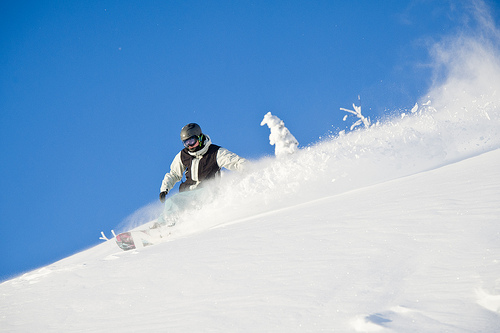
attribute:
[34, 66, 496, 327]
snow — white